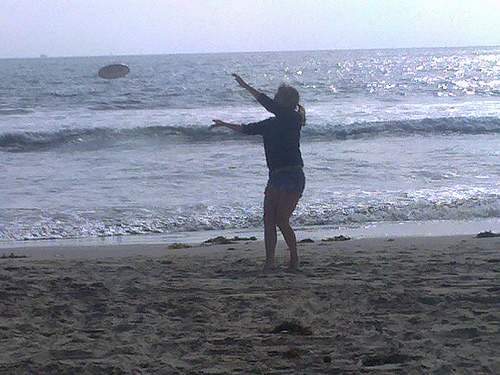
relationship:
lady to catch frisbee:
[216, 86, 320, 227] [41, 44, 149, 94]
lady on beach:
[206, 72, 306, 272] [10, 237, 494, 371]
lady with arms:
[206, 72, 306, 272] [231, 70, 274, 114]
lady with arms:
[206, 72, 306, 272] [206, 105, 264, 137]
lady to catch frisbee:
[206, 72, 306, 272] [85, 50, 139, 97]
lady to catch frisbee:
[206, 72, 306, 272] [93, 54, 133, 83]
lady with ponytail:
[206, 72, 306, 272] [292, 102, 309, 131]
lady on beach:
[206, 72, 306, 272] [2, 15, 499, 372]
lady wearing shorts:
[206, 72, 306, 272] [267, 162, 304, 194]